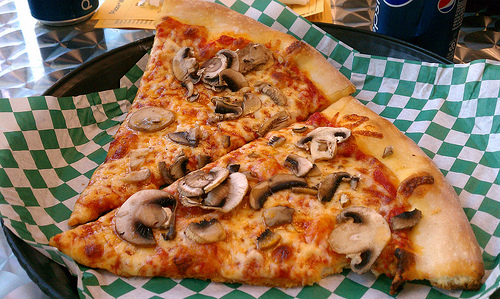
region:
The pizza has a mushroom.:
[102, 179, 174, 246]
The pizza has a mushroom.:
[176, 164, 231, 190]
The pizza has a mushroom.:
[186, 214, 220, 245]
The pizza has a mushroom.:
[324, 200, 389, 286]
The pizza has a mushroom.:
[296, 118, 343, 164]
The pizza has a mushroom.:
[128, 100, 169, 133]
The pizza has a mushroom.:
[169, 42, 198, 95]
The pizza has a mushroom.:
[212, 91, 284, 121]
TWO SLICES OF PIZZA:
[50, 12, 470, 297]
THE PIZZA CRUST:
[322, 90, 482, 293]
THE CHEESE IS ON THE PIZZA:
[58, 120, 418, 280]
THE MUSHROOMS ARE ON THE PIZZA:
[50, 101, 435, 287]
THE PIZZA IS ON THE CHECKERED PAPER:
[1, 0, 491, 295]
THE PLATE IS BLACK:
[3, 15, 358, 295]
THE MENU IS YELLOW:
[91, 0, 211, 48]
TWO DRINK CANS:
[23, 0, 473, 70]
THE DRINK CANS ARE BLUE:
[25, 0, 477, 66]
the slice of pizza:
[48, 92, 476, 296]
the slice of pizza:
[48, 0, 351, 216]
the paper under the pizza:
[0, 18, 489, 297]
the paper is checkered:
[2, 18, 497, 295]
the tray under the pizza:
[4, 26, 441, 293]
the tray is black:
[41, 12, 489, 294]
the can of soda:
[26, 0, 99, 19]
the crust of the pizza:
[211, 8, 329, 73]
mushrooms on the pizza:
[121, 187, 246, 233]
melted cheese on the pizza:
[143, 61, 191, 128]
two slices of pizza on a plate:
[47, 0, 499, 292]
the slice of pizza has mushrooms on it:
[73, 0, 358, 224]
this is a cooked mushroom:
[111, 188, 183, 249]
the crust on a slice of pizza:
[318, 93, 485, 298]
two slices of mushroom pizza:
[57, 8, 486, 295]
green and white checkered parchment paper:
[368, 58, 498, 118]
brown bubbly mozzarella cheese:
[115, 139, 165, 159]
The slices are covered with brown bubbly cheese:
[53, 3, 487, 287]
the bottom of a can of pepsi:
[365, 0, 464, 52]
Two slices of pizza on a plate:
[4, 4, 489, 297]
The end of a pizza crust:
[421, 256, 486, 290]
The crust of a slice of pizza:
[327, 92, 484, 289]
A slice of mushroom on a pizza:
[111, 185, 178, 250]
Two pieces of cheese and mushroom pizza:
[47, 3, 486, 293]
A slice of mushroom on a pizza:
[294, 121, 354, 163]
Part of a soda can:
[365, 1, 471, 60]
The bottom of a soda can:
[25, 1, 100, 28]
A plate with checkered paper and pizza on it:
[2, 5, 498, 295]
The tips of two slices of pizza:
[45, 206, 88, 262]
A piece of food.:
[111, 182, 178, 263]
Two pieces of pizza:
[43, 0, 485, 290]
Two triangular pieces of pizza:
[47, 0, 487, 290]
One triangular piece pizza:
[44, 93, 486, 291]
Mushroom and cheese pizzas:
[47, 0, 485, 297]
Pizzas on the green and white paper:
[1, 0, 499, 297]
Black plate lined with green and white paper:
[0, 0, 497, 297]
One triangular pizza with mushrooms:
[66, 0, 356, 227]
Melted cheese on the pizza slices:
[47, 0, 487, 297]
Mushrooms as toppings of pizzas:
[48, 0, 486, 296]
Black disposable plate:
[0, 20, 498, 297]